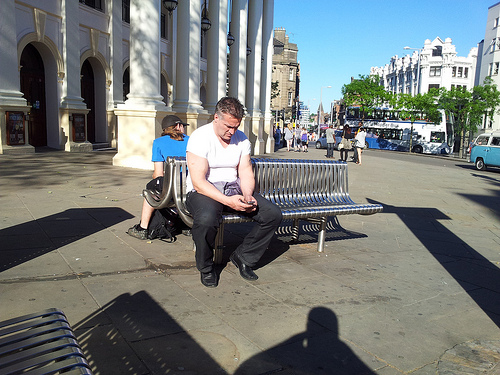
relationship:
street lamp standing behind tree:
[403, 45, 420, 152] [445, 82, 498, 157]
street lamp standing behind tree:
[403, 45, 420, 152] [392, 92, 433, 151]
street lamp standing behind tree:
[403, 45, 420, 152] [342, 75, 392, 132]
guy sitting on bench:
[182, 96, 284, 289] [173, 159, 382, 263]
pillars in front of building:
[227, 0, 252, 143] [0, 0, 274, 154]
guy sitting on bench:
[182, 96, 284, 289] [137, 155, 384, 252]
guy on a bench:
[179, 99, 288, 289] [137, 157, 384, 261]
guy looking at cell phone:
[182, 96, 284, 289] [247, 200, 256, 205]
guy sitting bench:
[182, 96, 284, 289] [263, 161, 383, 250]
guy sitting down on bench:
[182, 96, 284, 289] [176, 151, 384, 254]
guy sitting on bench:
[182, 96, 284, 289] [168, 153, 378, 262]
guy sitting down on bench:
[182, 96, 284, 289] [173, 159, 383, 249]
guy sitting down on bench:
[182, 96, 284, 289] [173, 152, 379, 272]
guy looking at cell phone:
[182, 96, 284, 289] [240, 190, 255, 209]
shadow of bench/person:
[3, 288, 398, 373] [137, 98, 383, 287]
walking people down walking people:
[353, 124, 367, 164] [338, 124, 352, 164]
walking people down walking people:
[353, 124, 367, 164] [323, 125, 337, 160]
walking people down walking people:
[353, 124, 367, 164] [301, 125, 310, 156]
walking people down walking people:
[353, 124, 367, 164] [294, 123, 301, 151]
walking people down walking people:
[353, 124, 367, 164] [282, 123, 292, 151]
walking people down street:
[353, 124, 367, 164] [280, 144, 497, 277]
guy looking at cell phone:
[182, 96, 284, 289] [237, 194, 258, 205]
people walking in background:
[275, 119, 366, 165] [273, 87, 432, 142]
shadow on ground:
[227, 305, 382, 374] [1, 135, 498, 374]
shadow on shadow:
[227, 305, 382, 374] [70, 288, 231, 373]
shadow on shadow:
[227, 305, 382, 374] [0, 201, 135, 276]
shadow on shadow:
[227, 305, 382, 374] [363, 194, 498, 329]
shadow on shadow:
[227, 305, 382, 374] [452, 184, 497, 226]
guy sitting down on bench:
[182, 96, 284, 289] [239, 149, 379, 254]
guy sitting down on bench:
[182, 96, 284, 289] [155, 120, 427, 277]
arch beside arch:
[16, 37, 64, 76] [79, 54, 110, 83]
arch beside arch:
[16, 37, 64, 76] [122, 65, 134, 83]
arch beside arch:
[16, 37, 64, 76] [158, 70, 170, 94]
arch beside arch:
[16, 37, 64, 76] [197, 84, 209, 102]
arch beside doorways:
[16, 37, 64, 76] [22, 37, 59, 153]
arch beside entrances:
[16, 37, 64, 76] [78, 55, 108, 150]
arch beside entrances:
[16, 37, 64, 76] [121, 64, 134, 106]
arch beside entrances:
[16, 37, 64, 76] [159, 70, 169, 110]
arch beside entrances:
[16, 37, 64, 76] [199, 85, 209, 112]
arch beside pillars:
[16, 37, 64, 76] [109, 0, 177, 172]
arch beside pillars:
[16, 37, 64, 76] [168, 0, 212, 137]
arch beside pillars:
[16, 37, 64, 76] [204, 0, 227, 125]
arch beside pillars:
[16, 37, 64, 76] [227, 0, 252, 143]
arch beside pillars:
[16, 37, 64, 76] [243, 0, 265, 157]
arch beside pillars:
[16, 37, 64, 76] [257, 0, 276, 156]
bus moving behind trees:
[342, 104, 453, 156] [342, 74, 497, 156]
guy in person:
[182, 96, 284, 289] [127, 113, 189, 239]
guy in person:
[182, 96, 284, 289] [353, 125, 368, 164]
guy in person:
[182, 96, 284, 289] [338, 122, 351, 162]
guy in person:
[182, 96, 284, 289] [324, 122, 338, 156]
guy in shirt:
[182, 96, 284, 289] [183, 120, 251, 191]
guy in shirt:
[182, 96, 284, 289] [152, 130, 189, 160]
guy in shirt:
[182, 96, 284, 289] [354, 131, 367, 147]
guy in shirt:
[182, 96, 284, 289] [324, 127, 335, 143]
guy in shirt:
[182, 96, 284, 289] [301, 133, 306, 138]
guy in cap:
[182, 96, 284, 289] [159, 112, 189, 126]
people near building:
[275, 119, 366, 165] [0, 0, 274, 172]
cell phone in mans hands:
[247, 200, 256, 205] [227, 194, 260, 214]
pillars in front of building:
[117, 6, 282, 166] [0, 0, 274, 154]